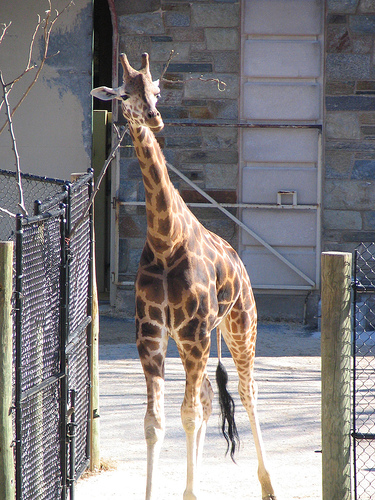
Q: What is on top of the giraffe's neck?
A: Its head.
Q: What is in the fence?
A: A giraffe.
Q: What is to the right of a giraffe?
A: A post.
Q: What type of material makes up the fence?
A: Chain link.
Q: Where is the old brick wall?
A: Behind the giraffe.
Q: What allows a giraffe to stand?
A: It's four legs.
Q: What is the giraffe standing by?
A: A gate.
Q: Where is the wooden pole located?
A: Attached to the fence.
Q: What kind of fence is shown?
A: Chain link.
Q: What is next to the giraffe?
A: Tree branches.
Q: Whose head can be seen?
A: The giraffe's head.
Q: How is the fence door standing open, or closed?
A: Open.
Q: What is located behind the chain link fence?
A: Tree limbs.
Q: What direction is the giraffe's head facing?
A: Forward.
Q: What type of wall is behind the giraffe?
A: Brick.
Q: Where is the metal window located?
A: In the brick wall.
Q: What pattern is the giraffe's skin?
A: Spotted.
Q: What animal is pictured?
A: Giraffe.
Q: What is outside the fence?
A: Tree branches.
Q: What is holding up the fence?
A: Wooden posts.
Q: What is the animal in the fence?
A: Giraffe.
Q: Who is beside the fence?
A: No one.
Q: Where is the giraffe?
A: In the fence.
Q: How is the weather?
A: Sunny.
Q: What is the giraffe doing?
A: Standing.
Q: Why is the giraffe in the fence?
A: So it won't run away.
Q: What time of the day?
A: Morning.